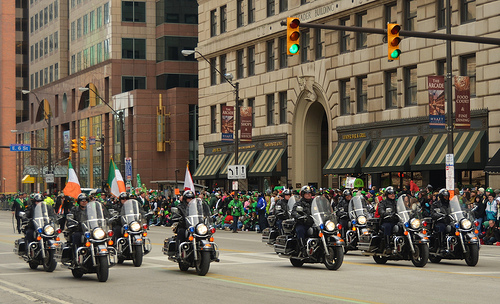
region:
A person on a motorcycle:
[156, 171, 207, 273]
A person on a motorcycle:
[111, 195, 157, 266]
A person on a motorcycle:
[61, 189, 118, 272]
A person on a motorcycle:
[6, 180, 68, 277]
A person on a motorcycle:
[285, 186, 347, 280]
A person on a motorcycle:
[381, 174, 426, 269]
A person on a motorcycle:
[436, 184, 486, 259]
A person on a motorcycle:
[274, 188, 297, 243]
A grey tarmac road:
[129, 264, 256, 297]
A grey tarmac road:
[257, 250, 417, 300]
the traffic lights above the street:
[277, 18, 498, 62]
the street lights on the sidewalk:
[180, 45, 238, 195]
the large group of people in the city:
[3, 159, 497, 280]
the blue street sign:
[9, 143, 31, 152]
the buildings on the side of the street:
[0, 0, 498, 192]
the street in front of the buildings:
[1, 208, 498, 303]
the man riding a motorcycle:
[272, 184, 344, 270]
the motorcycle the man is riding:
[273, 183, 343, 270]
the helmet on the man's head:
[300, 184, 312, 196]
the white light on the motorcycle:
[325, 219, 333, 231]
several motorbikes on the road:
[14, 163, 488, 278]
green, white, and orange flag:
[100, 153, 135, 205]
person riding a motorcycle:
[166, 182, 230, 279]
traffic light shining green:
[279, 12, 306, 59]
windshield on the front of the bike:
[309, 191, 336, 228]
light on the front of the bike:
[353, 213, 368, 227]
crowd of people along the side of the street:
[4, 172, 499, 242]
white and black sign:
[222, 161, 252, 181]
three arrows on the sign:
[221, 161, 252, 174]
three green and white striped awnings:
[321, 128, 486, 170]